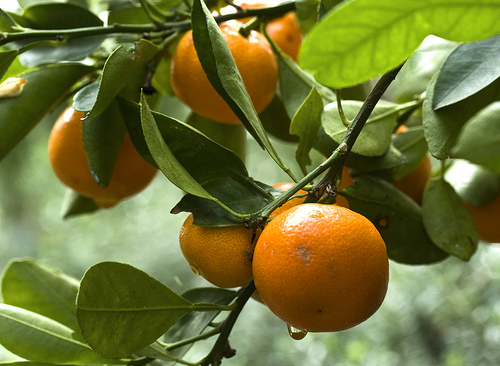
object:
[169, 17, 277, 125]
fruit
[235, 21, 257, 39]
stem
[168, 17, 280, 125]
orange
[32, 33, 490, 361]
tree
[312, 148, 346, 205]
stem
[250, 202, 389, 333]
fruit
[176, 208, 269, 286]
fruits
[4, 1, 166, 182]
leaves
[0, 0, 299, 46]
branch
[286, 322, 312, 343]
water drop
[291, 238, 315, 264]
bruise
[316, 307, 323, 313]
spot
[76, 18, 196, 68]
leave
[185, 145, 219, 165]
spot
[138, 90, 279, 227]
leaf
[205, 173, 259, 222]
lines